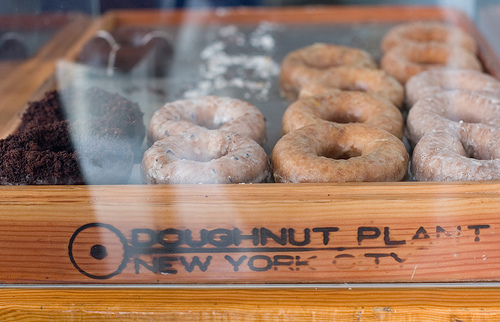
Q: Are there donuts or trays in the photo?
A: Yes, there is a donut.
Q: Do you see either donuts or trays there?
A: Yes, there is a donut.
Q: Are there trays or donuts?
A: Yes, there is a donut.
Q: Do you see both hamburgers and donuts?
A: No, there is a donut but no hamburgers.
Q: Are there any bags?
A: No, there are no bags.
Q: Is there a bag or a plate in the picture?
A: No, there are no bags or plates.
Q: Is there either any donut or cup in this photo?
A: Yes, there is a donut.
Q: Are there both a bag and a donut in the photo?
A: No, there is a donut but no bags.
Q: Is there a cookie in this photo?
A: No, there are no cookies.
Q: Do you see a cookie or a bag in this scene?
A: No, there are no cookies or bags.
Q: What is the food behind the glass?
A: The food is a donut.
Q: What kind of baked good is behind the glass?
A: The food is a donut.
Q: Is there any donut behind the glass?
A: Yes, there is a donut behind the glass.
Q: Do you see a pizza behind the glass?
A: No, there is a donut behind the glass.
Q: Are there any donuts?
A: Yes, there is a donut.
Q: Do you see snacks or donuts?
A: Yes, there is a donut.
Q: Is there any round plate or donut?
A: Yes, there is a round donut.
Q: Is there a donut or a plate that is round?
A: Yes, the donut is round.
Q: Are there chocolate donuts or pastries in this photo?
A: Yes, there is a chocolate donut.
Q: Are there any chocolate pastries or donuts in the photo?
A: Yes, there is a chocolate donut.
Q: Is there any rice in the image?
A: No, there is no rice.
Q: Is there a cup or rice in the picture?
A: No, there are no rice or cups.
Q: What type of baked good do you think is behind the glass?
A: The food is a donut.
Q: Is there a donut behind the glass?
A: Yes, there is a donut behind the glass.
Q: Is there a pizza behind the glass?
A: No, there is a donut behind the glass.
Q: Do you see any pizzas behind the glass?
A: No, there is a donut behind the glass.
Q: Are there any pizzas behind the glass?
A: No, there is a donut behind the glass.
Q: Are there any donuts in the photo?
A: Yes, there is a donut.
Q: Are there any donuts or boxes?
A: Yes, there is a donut.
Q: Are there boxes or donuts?
A: Yes, there is a donut.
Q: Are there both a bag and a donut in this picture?
A: No, there is a donut but no bags.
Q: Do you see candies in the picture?
A: No, there are no candies.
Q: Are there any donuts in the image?
A: Yes, there is a donut.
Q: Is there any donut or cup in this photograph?
A: Yes, there is a donut.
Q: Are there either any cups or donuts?
A: Yes, there is a donut.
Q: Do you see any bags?
A: No, there are no bags.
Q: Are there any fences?
A: No, there are no fences.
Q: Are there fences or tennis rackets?
A: No, there are no fences or tennis rackets.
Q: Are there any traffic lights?
A: No, there are no traffic lights.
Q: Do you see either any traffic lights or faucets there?
A: No, there are no traffic lights or faucets.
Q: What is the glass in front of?
A: The glass is in front of the donut.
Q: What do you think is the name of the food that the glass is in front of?
A: The food is a donut.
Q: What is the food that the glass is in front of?
A: The food is a donut.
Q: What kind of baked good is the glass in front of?
A: The glass is in front of the donut.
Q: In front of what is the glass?
A: The glass is in front of the doughnut.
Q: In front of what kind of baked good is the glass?
A: The glass is in front of the doughnut.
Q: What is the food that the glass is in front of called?
A: The food is a donut.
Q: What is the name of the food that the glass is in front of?
A: The food is a donut.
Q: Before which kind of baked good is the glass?
A: The glass is in front of the doughnut.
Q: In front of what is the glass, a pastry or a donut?
A: The glass is in front of a donut.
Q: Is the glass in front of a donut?
A: Yes, the glass is in front of a donut.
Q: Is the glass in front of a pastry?
A: No, the glass is in front of a donut.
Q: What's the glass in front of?
A: The glass is in front of the doughnut.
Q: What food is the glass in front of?
A: The glass is in front of the donut.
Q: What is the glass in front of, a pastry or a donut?
A: The glass is in front of a donut.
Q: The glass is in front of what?
A: The glass is in front of the donut.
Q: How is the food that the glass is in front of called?
A: The food is a donut.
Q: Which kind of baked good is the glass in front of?
A: The glass is in front of the donut.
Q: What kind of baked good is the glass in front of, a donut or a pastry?
A: The glass is in front of a donut.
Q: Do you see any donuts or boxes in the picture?
A: Yes, there is a donut.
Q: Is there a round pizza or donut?
A: Yes, there is a round donut.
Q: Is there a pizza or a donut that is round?
A: Yes, the donut is round.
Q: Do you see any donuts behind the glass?
A: Yes, there is a donut behind the glass.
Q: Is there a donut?
A: Yes, there is a donut.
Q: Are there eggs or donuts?
A: Yes, there is a donut.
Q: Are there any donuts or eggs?
A: Yes, there is a donut.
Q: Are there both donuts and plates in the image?
A: No, there is a donut but no plates.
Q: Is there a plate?
A: No, there are no plates.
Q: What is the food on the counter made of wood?
A: The food is a donut.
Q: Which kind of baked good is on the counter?
A: The food is a donut.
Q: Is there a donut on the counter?
A: Yes, there is a donut on the counter.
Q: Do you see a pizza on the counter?
A: No, there is a donut on the counter.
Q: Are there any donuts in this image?
A: Yes, there is a donut.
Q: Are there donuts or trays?
A: Yes, there is a donut.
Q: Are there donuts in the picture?
A: Yes, there is a donut.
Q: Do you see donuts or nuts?
A: Yes, there is a donut.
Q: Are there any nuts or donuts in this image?
A: Yes, there is a donut.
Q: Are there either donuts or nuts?
A: Yes, there is a donut.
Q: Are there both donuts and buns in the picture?
A: No, there is a donut but no buns.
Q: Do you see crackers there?
A: No, there are no crackers.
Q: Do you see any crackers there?
A: No, there are no crackers.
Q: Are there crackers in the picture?
A: No, there are no crackers.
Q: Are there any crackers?
A: No, there are no crackers.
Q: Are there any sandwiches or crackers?
A: No, there are no crackers or sandwiches.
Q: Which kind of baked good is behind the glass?
A: The food is a donut.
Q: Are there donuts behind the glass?
A: Yes, there is a donut behind the glass.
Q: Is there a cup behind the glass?
A: No, there is a donut behind the glass.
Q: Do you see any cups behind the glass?
A: No, there is a donut behind the glass.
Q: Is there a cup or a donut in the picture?
A: Yes, there is a donut.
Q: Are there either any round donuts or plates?
A: Yes, there is a round donut.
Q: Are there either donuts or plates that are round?
A: Yes, the donut is round.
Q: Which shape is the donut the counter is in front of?
A: The donut is round.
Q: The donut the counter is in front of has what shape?
A: The donut is round.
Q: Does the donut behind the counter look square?
A: No, the donut is round.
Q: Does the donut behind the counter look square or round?
A: The donut is round.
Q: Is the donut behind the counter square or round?
A: The donut is round.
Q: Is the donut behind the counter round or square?
A: The donut is round.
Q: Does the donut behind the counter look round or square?
A: The donut is round.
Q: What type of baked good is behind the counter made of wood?
A: The food is a donut.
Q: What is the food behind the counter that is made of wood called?
A: The food is a donut.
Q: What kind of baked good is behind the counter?
A: The food is a donut.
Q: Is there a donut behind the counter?
A: Yes, there is a donut behind the counter.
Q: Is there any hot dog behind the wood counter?
A: No, there is a donut behind the counter.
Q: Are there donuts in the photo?
A: Yes, there is a donut.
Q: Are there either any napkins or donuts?
A: Yes, there is a donut.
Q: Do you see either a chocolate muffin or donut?
A: Yes, there is a chocolate donut.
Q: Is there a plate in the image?
A: No, there are no plates.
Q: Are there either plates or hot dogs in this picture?
A: No, there are no plates or hot dogs.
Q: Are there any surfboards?
A: No, there are no surfboards.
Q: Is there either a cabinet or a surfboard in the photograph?
A: No, there are no surfboards or cabinets.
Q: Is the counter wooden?
A: Yes, the counter is wooden.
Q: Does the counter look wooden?
A: Yes, the counter is wooden.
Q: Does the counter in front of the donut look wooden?
A: Yes, the counter is wooden.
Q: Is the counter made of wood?
A: Yes, the counter is made of wood.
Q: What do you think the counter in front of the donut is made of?
A: The counter is made of wood.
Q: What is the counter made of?
A: The counter is made of wood.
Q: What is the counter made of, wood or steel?
A: The counter is made of wood.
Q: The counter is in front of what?
A: The counter is in front of the donut.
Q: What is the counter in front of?
A: The counter is in front of the donut.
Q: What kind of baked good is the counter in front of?
A: The counter is in front of the donut.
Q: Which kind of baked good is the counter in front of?
A: The counter is in front of the donut.